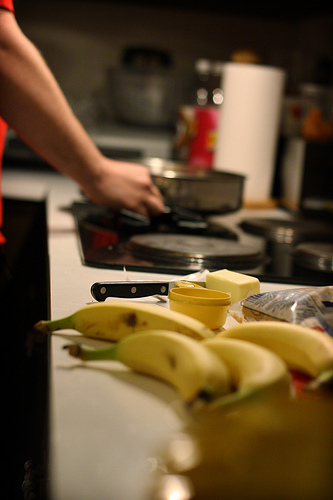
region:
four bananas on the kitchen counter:
[34, 298, 328, 414]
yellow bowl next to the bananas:
[166, 287, 229, 328]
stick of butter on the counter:
[203, 267, 256, 298]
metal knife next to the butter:
[89, 279, 212, 301]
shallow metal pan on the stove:
[127, 156, 245, 210]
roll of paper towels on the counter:
[214, 65, 284, 203]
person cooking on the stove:
[0, 0, 164, 252]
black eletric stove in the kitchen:
[73, 210, 328, 278]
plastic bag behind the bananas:
[225, 286, 332, 327]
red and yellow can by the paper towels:
[188, 109, 216, 167]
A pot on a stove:
[114, 149, 260, 237]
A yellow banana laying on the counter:
[62, 327, 234, 406]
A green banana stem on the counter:
[29, 305, 81, 335]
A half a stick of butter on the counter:
[201, 262, 263, 305]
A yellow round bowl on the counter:
[164, 282, 237, 335]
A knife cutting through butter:
[80, 267, 226, 303]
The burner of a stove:
[115, 221, 282, 276]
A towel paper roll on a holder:
[211, 55, 290, 220]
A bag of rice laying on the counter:
[224, 277, 331, 346]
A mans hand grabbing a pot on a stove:
[0, 1, 253, 236]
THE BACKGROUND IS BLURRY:
[131, 58, 294, 207]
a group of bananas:
[122, 322, 240, 398]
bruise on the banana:
[113, 313, 143, 332]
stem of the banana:
[43, 313, 88, 329]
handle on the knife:
[89, 279, 174, 295]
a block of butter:
[213, 274, 247, 290]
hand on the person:
[95, 156, 155, 207]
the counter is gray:
[71, 433, 127, 493]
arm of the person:
[9, 62, 74, 150]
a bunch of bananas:
[104, 290, 299, 399]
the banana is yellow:
[196, 363, 206, 377]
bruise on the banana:
[116, 304, 145, 332]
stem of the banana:
[61, 339, 119, 367]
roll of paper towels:
[213, 68, 283, 191]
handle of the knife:
[85, 274, 171, 301]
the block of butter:
[215, 266, 253, 297]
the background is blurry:
[86, 20, 273, 152]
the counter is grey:
[78, 425, 121, 460]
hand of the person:
[76, 157, 170, 218]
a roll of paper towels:
[223, 51, 297, 202]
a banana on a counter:
[50, 290, 213, 347]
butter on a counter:
[202, 264, 267, 296]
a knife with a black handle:
[93, 269, 209, 305]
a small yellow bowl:
[157, 278, 238, 330]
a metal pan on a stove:
[118, 170, 245, 220]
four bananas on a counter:
[50, 303, 326, 430]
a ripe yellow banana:
[29, 302, 206, 352]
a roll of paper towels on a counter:
[215, 43, 293, 214]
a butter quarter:
[205, 268, 264, 300]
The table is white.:
[88, 390, 137, 441]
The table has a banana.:
[50, 291, 213, 352]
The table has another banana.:
[86, 338, 223, 416]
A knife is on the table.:
[92, 260, 204, 308]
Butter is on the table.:
[205, 258, 259, 309]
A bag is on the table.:
[255, 285, 327, 338]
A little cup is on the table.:
[161, 276, 227, 330]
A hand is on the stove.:
[88, 141, 157, 230]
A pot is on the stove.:
[152, 161, 251, 219]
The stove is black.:
[129, 220, 257, 262]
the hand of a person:
[88, 159, 157, 227]